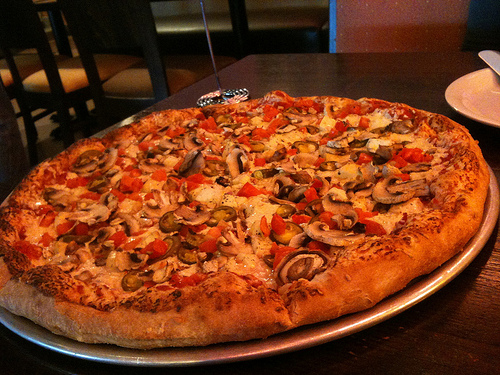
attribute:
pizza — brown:
[5, 74, 488, 362]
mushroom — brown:
[263, 235, 336, 307]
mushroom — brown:
[274, 234, 350, 286]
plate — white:
[440, 66, 496, 125]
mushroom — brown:
[270, 250, 330, 287]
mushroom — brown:
[271, 242, 331, 285]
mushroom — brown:
[275, 247, 329, 291]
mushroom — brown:
[274, 246, 325, 282]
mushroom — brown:
[277, 245, 331, 287]